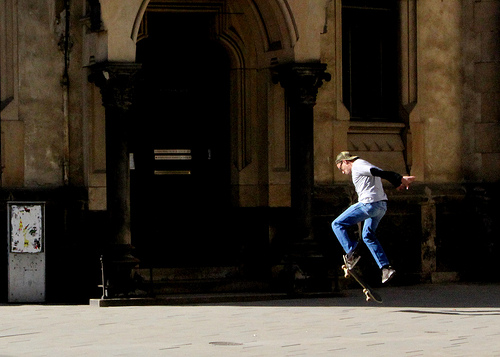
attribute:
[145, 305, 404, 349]
ground — concrete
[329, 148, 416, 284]
skater — looking down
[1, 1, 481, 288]
building — old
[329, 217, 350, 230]
knee — bend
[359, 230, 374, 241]
knee — bend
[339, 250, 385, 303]
skateboard — black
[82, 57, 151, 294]
column — brown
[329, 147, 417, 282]
man — jumping, airborne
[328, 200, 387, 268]
jeans — blue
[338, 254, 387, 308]
skateboard — airborne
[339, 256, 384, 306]
skateboard — airborne, tilted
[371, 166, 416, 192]
arms — extended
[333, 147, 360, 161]
hat — backwards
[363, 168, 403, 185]
sleeves — black, long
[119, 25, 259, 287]
doorway — arched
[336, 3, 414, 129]
window — dark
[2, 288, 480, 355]
surface — paved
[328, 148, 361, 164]
hat — backwards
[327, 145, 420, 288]
man — black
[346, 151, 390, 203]
shirt — gray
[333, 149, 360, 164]
hat — green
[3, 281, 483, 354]
ground — gray, concrete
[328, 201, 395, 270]
jeans — blue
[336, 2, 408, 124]
window — large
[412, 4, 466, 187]
wall — brown, stone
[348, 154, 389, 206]
t-shirt — gray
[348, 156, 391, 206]
shirt — gray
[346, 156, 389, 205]
shirt — black,  long sleeves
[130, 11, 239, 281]
door —  large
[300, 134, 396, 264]
skate — mid air